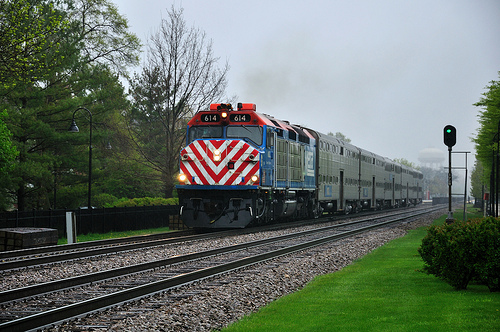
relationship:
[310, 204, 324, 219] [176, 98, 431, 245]
wheel on train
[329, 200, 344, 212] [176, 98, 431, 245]
wheel on train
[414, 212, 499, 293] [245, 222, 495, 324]
bush on space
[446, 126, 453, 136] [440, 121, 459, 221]
light on pole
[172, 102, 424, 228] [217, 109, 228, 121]
train has light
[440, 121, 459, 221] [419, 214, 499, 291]
pole behind bush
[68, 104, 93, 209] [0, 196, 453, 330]
street light alongside track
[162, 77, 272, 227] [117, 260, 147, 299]
train on track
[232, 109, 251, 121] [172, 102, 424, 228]
numbers on train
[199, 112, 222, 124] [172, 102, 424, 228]
numbers on train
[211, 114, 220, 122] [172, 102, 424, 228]
number 4 on train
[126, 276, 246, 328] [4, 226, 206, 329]
rocks by tracks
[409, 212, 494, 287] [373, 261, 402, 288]
bush by grass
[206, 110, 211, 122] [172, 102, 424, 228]
number 1 on train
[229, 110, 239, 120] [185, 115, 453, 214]
number on train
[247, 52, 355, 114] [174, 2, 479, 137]
smoke in sky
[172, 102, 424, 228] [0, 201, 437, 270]
train on track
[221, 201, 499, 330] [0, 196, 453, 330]
green space near track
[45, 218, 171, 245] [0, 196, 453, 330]
green space near track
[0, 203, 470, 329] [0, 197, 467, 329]
rocks near tracks